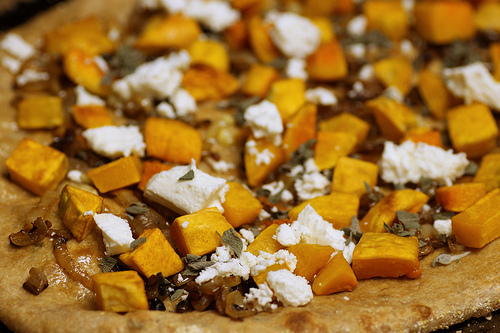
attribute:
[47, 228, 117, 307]
onion — cut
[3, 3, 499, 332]
pita — cooked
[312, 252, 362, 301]
cheese — orange, white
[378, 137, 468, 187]
cheese — white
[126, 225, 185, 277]
potato — orange